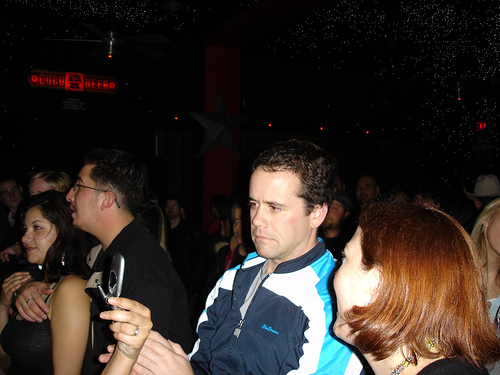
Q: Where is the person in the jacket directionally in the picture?
A: Center.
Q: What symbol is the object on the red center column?
A: Star.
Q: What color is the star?
A: Silver.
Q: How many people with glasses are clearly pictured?
A: One.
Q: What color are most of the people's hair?
A: Black.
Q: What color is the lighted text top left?
A: Red.